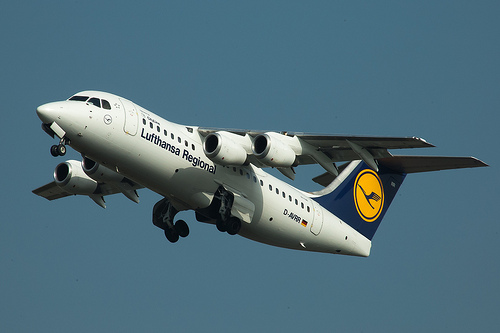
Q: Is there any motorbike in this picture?
A: No, there are no motorcycles.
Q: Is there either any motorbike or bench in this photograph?
A: No, there are no motorcycles or benches.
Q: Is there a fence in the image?
A: No, there are no fences.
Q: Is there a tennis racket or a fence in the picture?
A: No, there are no fences or rackets.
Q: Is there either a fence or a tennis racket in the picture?
A: No, there are no fences or rackets.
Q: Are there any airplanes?
A: Yes, there is an airplane.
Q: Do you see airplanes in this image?
A: Yes, there is an airplane.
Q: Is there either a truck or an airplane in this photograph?
A: Yes, there is an airplane.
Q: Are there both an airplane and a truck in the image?
A: No, there is an airplane but no trucks.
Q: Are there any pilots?
A: No, there are no pilots.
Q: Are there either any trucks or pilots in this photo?
A: No, there are no pilots or trucks.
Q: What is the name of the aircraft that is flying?
A: The aircraft is an airplane.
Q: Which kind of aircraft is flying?
A: The aircraft is an airplane.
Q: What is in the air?
A: The plane is in the air.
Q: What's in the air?
A: The plane is in the air.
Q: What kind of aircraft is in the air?
A: The aircraft is an airplane.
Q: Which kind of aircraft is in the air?
A: The aircraft is an airplane.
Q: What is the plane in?
A: The plane is in the air.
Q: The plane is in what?
A: The plane is in the air.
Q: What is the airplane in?
A: The plane is in the air.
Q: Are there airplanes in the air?
A: Yes, there is an airplane in the air.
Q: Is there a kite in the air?
A: No, there is an airplane in the air.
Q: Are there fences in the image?
A: No, there are no fences.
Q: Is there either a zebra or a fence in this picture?
A: No, there are no fences or zebras.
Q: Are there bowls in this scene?
A: No, there are no bowls.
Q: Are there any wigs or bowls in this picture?
A: No, there are no bowls or wigs.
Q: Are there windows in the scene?
A: Yes, there is a window.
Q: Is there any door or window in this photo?
A: Yes, there is a window.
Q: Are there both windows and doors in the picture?
A: Yes, there are both a window and a door.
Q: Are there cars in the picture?
A: No, there are no cars.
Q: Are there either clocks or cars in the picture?
A: No, there are no cars or clocks.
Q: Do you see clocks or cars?
A: No, there are no cars or clocks.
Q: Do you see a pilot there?
A: No, there are no pilots.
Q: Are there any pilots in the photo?
A: No, there are no pilots.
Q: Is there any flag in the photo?
A: Yes, there is a flag.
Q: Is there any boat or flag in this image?
A: Yes, there is a flag.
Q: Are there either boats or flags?
A: Yes, there is a flag.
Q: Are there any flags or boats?
A: Yes, there is a flag.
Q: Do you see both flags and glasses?
A: No, there is a flag but no glasses.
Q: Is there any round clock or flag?
A: Yes, there is a round flag.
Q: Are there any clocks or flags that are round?
A: Yes, the flag is round.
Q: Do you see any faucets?
A: No, there are no faucets.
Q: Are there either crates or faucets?
A: No, there are no faucets or crates.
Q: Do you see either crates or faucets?
A: No, there are no faucets or crates.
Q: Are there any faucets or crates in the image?
A: No, there are no faucets or crates.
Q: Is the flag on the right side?
A: Yes, the flag is on the right of the image.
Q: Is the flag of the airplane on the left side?
A: No, the flag is on the right of the image.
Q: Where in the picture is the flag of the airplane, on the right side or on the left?
A: The flag is on the right of the image.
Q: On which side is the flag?
A: The flag is on the right of the image.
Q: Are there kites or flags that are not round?
A: No, there is a flag but it is round.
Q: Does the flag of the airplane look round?
A: Yes, the flag is round.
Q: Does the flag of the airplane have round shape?
A: Yes, the flag is round.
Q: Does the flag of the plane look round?
A: Yes, the flag is round.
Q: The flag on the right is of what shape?
A: The flag is round.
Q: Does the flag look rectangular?
A: No, the flag is round.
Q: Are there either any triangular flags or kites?
A: No, there is a flag but it is round.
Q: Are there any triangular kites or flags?
A: No, there is a flag but it is round.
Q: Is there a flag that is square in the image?
A: No, there is a flag but it is round.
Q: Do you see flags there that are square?
A: No, there is a flag but it is round.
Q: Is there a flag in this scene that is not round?
A: No, there is a flag but it is round.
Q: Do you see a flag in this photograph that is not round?
A: No, there is a flag but it is round.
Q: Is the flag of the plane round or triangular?
A: The flag is round.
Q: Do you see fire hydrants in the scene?
A: No, there are no fire hydrants.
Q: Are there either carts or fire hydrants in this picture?
A: No, there are no fire hydrants or carts.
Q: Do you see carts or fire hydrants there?
A: No, there are no fire hydrants or carts.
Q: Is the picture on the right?
A: Yes, the picture is on the right of the image.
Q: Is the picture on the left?
A: No, the picture is on the right of the image.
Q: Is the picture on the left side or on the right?
A: The picture is on the right of the image.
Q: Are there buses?
A: No, there are no buses.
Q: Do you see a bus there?
A: No, there are no buses.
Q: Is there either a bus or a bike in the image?
A: No, there are no buses or bikes.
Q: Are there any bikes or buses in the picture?
A: No, there are no buses or bikes.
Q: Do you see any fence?
A: No, there are no fences.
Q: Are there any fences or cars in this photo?
A: No, there are no fences or cars.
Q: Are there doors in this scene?
A: Yes, there is a door.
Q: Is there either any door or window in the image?
A: Yes, there is a door.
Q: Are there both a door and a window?
A: Yes, there are both a door and a window.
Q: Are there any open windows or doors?
A: Yes, there is an open door.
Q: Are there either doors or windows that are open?
A: Yes, the door is open.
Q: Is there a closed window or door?
A: Yes, there is a closed door.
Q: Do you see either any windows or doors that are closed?
A: Yes, the door is closed.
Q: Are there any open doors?
A: Yes, there is an open door.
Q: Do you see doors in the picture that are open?
A: Yes, there is an open door.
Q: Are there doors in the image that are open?
A: Yes, there is a door that is open.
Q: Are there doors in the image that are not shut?
A: Yes, there is a open door.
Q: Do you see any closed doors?
A: Yes, there is a closed door.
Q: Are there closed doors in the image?
A: Yes, there is a closed door.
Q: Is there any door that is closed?
A: Yes, there is a door that is closed.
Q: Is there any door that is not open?
A: Yes, there is an closed door.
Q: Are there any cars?
A: No, there are no cars.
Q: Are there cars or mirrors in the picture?
A: No, there are no cars or mirrors.